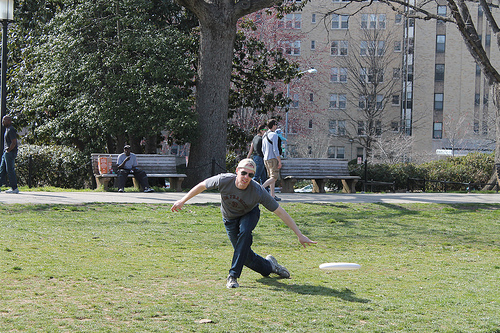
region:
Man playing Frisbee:
[170, 158, 318, 289]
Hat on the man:
[235, 157, 256, 175]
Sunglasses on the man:
[236, 166, 255, 178]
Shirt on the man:
[202, 173, 279, 223]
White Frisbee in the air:
[317, 261, 359, 270]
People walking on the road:
[0, 114, 282, 201]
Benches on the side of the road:
[87, 152, 358, 194]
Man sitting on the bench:
[115, 144, 146, 194]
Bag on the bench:
[95, 150, 114, 175]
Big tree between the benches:
[177, 0, 272, 191]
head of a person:
[233, 156, 261, 188]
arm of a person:
[263, 195, 320, 255]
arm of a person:
[176, 156, 221, 204]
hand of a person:
[165, 203, 182, 223]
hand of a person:
[300, 238, 315, 249]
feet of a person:
[216, 259, 248, 294]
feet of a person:
[262, 246, 294, 278]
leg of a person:
[215, 211, 285, 298]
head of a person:
[262, 115, 277, 133]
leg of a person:
[259, 158, 283, 193]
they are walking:
[249, 114, 289, 202]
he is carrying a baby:
[272, 125, 287, 156]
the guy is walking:
[1, 111, 21, 199]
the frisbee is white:
[322, 258, 364, 278]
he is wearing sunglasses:
[238, 168, 255, 183]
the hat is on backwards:
[236, 153, 258, 177]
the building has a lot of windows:
[326, 34, 376, 116]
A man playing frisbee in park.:
[166, 155, 319, 301]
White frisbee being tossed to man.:
[316, 258, 363, 273]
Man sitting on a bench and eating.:
[115, 143, 156, 196]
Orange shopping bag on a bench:
[94, 153, 115, 177]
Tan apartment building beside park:
[226, 0, 498, 161]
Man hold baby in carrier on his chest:
[257, 117, 289, 203]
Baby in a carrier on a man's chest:
[273, 126, 288, 156]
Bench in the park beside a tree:
[88, 152, 190, 191]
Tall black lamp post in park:
[0, 0, 17, 190]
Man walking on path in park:
[0, 113, 21, 198]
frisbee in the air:
[303, 241, 391, 302]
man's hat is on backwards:
[223, 153, 276, 171]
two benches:
[75, 145, 383, 200]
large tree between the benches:
[189, 14, 241, 210]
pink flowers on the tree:
[237, 0, 352, 149]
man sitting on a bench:
[110, 144, 169, 194]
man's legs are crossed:
[202, 208, 305, 295]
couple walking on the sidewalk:
[241, 118, 298, 200]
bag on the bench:
[91, 151, 114, 180]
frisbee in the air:
[300, 251, 365, 282]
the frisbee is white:
[308, 253, 370, 284]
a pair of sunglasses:
[232, 163, 257, 185]